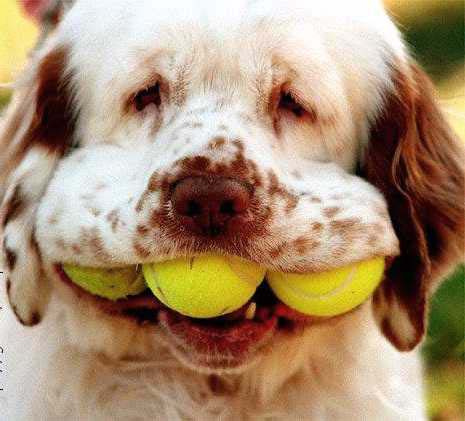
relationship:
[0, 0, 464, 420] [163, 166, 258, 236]
dog has nose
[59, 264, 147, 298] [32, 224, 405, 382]
balls in mouth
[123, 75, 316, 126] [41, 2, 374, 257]
eyes on dog's face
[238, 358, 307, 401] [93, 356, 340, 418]
fur on neck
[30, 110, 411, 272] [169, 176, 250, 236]
spots on nose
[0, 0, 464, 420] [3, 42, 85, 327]
dog has ear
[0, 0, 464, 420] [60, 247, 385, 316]
dog has balls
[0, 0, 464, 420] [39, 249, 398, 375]
dog has mouth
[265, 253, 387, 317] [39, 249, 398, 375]
balls in mouth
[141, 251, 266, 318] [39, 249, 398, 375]
ball in mouth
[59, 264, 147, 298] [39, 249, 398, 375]
balls in mouth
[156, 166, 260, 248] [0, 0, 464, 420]
nose on dog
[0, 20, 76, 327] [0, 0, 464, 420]
ear on dog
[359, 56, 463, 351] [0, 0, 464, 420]
ear on dog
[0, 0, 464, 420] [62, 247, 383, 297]
dog has balls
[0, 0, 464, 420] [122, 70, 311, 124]
dog has eyes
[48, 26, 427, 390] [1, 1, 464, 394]
dog has head